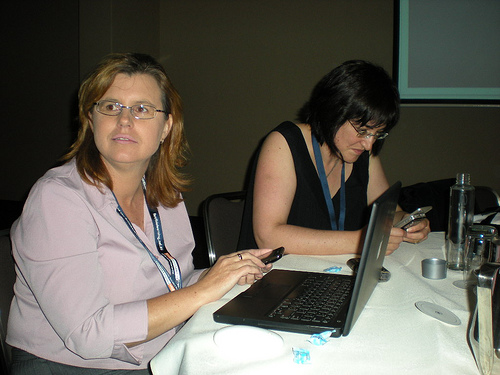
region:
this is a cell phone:
[226, 234, 299, 280]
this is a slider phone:
[387, 182, 443, 238]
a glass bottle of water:
[437, 162, 482, 292]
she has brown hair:
[45, 31, 232, 316]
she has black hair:
[275, 23, 399, 236]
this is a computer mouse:
[204, 320, 294, 360]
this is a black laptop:
[197, 175, 428, 340]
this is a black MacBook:
[206, 175, 409, 351]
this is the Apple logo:
[369, 220, 391, 271]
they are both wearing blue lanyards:
[37, 17, 477, 369]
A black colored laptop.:
[211, 178, 405, 339]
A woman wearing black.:
[236, 59, 431, 256]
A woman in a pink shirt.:
[1, 50, 275, 373]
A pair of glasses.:
[89, 98, 167, 120]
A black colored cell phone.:
[256, 246, 287, 262]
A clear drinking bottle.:
[446, 168, 478, 272]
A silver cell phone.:
[393, 203, 433, 228]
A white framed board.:
[394, 0, 499, 105]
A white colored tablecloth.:
[148, 230, 498, 374]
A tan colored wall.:
[1, 0, 394, 221]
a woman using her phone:
[12, 45, 290, 372]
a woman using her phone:
[225, 45, 443, 278]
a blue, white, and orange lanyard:
[90, 151, 200, 335]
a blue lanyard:
[298, 96, 352, 251]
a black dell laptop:
[205, 176, 400, 356]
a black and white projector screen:
[382, 0, 497, 120]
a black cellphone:
[252, 244, 292, 271]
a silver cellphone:
[395, 197, 427, 236]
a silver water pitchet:
[467, 232, 494, 369]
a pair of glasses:
[347, 115, 389, 147]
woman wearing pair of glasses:
[80, 50, 187, 179]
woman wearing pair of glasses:
[311, 58, 391, 162]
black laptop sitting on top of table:
[211, 182, 395, 336]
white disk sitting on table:
[411, 296, 463, 329]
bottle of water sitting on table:
[442, 168, 473, 269]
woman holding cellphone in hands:
[250, 60, 432, 255]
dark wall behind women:
[4, 0, 389, 74]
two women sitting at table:
[8, 53, 493, 370]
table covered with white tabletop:
[150, 222, 498, 372]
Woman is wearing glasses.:
[0, 49, 286, 374]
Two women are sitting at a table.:
[0, 49, 499, 374]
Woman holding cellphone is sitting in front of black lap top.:
[2, 49, 402, 374]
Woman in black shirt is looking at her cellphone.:
[230, 55, 432, 257]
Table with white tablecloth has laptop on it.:
[145, 173, 498, 373]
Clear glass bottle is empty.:
[441, 168, 475, 273]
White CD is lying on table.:
[147, 220, 497, 373]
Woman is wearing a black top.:
[230, 57, 434, 259]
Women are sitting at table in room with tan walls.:
[0, 0, 499, 374]